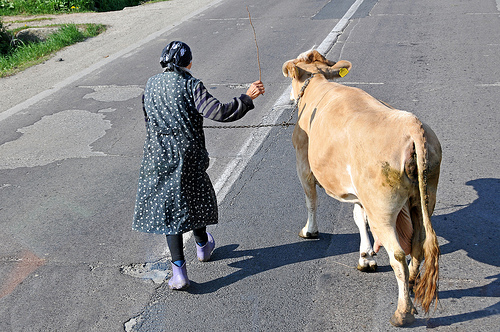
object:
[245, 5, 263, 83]
stick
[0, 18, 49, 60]
patch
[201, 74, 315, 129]
chain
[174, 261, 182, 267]
sock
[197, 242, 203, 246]
sock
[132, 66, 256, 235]
coat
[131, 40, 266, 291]
lady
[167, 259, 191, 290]
gray sneakers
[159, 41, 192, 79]
scarf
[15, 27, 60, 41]
gray rock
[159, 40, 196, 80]
bandana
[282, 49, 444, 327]
cow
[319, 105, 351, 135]
skin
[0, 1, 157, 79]
grass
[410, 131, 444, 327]
tail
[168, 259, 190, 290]
boot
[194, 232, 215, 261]
boot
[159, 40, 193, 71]
head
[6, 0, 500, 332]
road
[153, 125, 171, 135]
mid-section